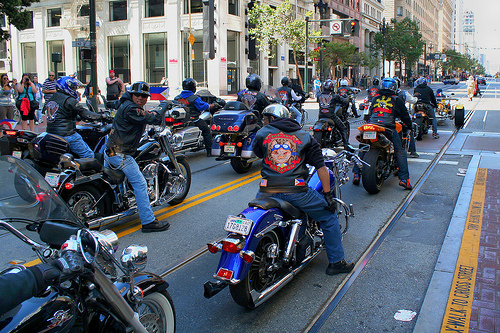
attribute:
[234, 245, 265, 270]
light — right tail, motorcycle's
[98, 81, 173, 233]
man — looking back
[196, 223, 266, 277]
light — red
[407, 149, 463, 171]
line — white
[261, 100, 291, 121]
helmet — silver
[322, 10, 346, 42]
sign — white, black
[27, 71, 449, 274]
motorcycles — several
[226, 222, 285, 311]
wheel — four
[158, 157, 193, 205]
wheel — four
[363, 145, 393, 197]
wheel — four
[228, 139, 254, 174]
wheel — four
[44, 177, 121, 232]
wheel — four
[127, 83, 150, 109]
head — turned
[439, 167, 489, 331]
line — yellow, safety